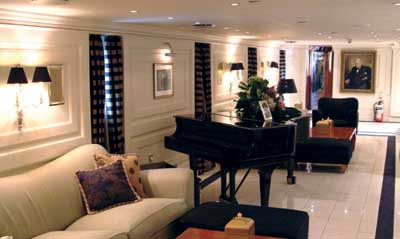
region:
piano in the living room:
[165, 88, 304, 195]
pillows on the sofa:
[71, 142, 144, 212]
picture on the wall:
[336, 45, 380, 101]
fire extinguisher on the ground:
[374, 95, 386, 124]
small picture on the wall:
[147, 56, 180, 105]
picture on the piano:
[258, 94, 278, 127]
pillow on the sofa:
[70, 155, 155, 207]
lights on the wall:
[2, 55, 54, 128]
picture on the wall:
[148, 59, 178, 101]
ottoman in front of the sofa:
[184, 189, 312, 231]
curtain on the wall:
[87, 32, 128, 152]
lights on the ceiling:
[224, 1, 354, 47]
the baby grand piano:
[162, 93, 311, 218]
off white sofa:
[2, 141, 195, 237]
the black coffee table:
[159, 197, 313, 237]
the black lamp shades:
[4, 63, 298, 94]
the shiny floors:
[194, 133, 393, 237]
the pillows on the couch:
[75, 149, 147, 214]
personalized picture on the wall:
[338, 47, 379, 96]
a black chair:
[310, 93, 360, 126]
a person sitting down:
[233, 71, 279, 120]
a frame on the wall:
[151, 59, 176, 101]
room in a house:
[12, 43, 377, 209]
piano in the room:
[158, 100, 301, 182]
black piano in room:
[173, 91, 298, 175]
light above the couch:
[7, 52, 64, 117]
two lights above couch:
[5, 57, 65, 106]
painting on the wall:
[326, 48, 382, 104]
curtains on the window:
[75, 28, 137, 114]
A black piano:
[164, 111, 297, 207]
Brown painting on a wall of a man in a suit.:
[339, 47, 377, 95]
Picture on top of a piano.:
[257, 99, 272, 121]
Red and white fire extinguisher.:
[372, 97, 385, 122]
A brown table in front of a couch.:
[173, 225, 276, 238]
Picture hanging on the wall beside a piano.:
[153, 62, 174, 99]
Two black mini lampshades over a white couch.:
[7, 64, 51, 83]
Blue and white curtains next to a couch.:
[88, 32, 126, 154]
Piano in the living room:
[156, 86, 301, 207]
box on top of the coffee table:
[312, 113, 338, 130]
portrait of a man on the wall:
[331, 44, 383, 103]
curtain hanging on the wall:
[188, 39, 217, 120]